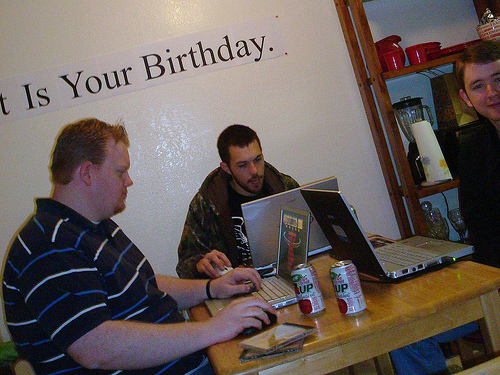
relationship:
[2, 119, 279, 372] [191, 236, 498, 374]
man sitting at table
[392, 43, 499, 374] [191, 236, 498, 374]
man sitting at table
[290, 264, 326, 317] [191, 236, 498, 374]
soda can on table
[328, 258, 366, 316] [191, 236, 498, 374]
soda can on table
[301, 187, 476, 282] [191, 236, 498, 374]
laptop on table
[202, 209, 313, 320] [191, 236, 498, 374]
laptops on table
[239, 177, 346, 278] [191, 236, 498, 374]
laptop on table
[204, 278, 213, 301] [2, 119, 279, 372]
bracelet on wrist of man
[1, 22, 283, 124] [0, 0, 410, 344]
sign on wall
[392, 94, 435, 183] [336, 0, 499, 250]
blender on shelf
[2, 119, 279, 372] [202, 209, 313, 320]
man working on laptops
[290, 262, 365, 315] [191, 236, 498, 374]
cans sitting on table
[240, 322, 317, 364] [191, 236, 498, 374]
disks sitting on table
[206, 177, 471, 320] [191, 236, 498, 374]
laptops sitting on table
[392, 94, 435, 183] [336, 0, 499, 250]
blender sitting on shelf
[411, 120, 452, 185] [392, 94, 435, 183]
towel paper sitting in front of blender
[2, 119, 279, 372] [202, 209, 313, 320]
man on laptops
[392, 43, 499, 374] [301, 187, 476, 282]
man on laptop